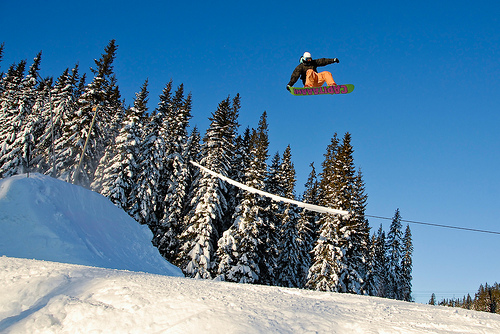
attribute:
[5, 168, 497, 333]
snow — white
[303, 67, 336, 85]
pant — orange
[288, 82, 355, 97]
drsnowboard — green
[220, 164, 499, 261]
powerline — black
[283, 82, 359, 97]
snowboard — green, pink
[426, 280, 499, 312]
tree group — green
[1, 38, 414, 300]
tree group — green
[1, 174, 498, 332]
white snow — deep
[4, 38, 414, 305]
trees — evergreen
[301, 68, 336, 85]
pants — orange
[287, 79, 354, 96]
snowboard — flying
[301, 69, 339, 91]
snow pants — orange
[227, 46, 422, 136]
snowboard — green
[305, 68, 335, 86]
pants — orange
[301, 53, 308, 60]
hat — white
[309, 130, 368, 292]
tree — tall, pine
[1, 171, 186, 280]
snowbank — piled up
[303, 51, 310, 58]
helmet — white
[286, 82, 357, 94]
snowboard — red, green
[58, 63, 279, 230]
tree — pine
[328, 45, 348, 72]
glove — black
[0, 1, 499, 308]
sky — clear, blue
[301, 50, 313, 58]
helmet — white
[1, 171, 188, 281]
hill — small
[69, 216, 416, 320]
snow — lots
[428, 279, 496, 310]
trees — bare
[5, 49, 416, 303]
tree — pine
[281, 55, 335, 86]
jacket — black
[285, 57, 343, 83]
jacket — Black  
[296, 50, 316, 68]
head — person's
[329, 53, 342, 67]
hand — person's